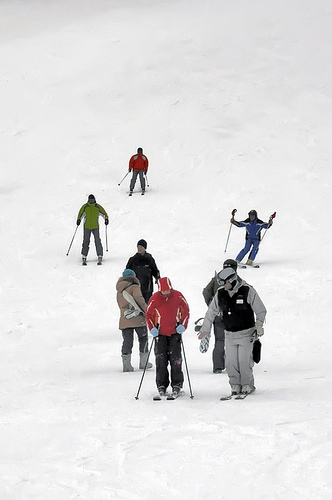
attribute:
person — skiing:
[68, 193, 112, 266]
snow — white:
[3, 1, 329, 500]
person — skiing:
[220, 206, 276, 263]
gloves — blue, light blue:
[150, 325, 184, 336]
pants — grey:
[226, 330, 254, 388]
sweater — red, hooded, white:
[143, 276, 190, 332]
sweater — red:
[130, 155, 151, 176]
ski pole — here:
[221, 212, 236, 250]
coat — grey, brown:
[118, 279, 146, 330]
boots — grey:
[122, 351, 154, 375]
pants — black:
[152, 335, 186, 397]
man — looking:
[125, 239, 161, 298]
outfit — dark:
[126, 252, 162, 296]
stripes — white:
[147, 279, 191, 326]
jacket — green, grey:
[74, 205, 108, 232]